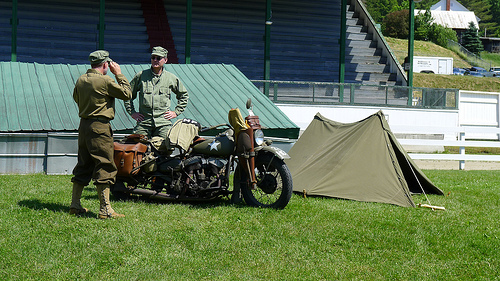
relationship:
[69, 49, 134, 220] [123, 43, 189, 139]
soldier salutes soldier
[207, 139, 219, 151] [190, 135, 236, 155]
star on tank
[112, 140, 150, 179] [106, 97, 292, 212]
bag on motorcycle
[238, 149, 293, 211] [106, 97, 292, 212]
wheel on motorcycle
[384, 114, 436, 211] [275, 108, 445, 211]
rope attached to tent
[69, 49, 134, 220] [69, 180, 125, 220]
soldier wears boots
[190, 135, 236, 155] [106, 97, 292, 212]
tank on motorcycle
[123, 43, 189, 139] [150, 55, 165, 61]
soldier wears sunglasses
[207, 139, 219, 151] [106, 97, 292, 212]
star on motorcycle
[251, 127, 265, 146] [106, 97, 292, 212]
headlight on motorcycle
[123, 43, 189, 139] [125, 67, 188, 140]
soldier wears uniform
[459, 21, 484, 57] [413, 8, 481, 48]
tree next to house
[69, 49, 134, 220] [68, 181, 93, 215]
soldier wears boot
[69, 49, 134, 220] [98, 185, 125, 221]
soldier wears boot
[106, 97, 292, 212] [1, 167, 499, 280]
motorcycle parked on grass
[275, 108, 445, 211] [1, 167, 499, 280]
tent on grass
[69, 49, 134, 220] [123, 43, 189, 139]
soldier talks to soldier